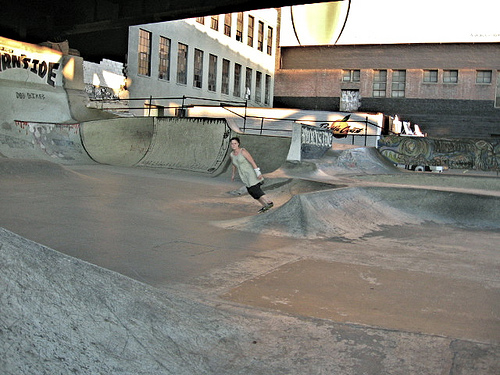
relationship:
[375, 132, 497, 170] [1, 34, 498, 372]
graffiti of skate park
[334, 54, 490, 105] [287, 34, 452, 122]
windows on building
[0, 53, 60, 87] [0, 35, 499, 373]
black letters in front a track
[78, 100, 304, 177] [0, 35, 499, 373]
ramp on track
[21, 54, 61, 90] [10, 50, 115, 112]
word: side on wall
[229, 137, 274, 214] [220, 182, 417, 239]
skateboarder skateboarding on ramp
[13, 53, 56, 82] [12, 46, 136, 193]
words on wall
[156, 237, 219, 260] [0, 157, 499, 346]
gray square on ground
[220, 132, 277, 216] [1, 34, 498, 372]
skateboarder in skate park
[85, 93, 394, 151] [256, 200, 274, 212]
railings in skateboard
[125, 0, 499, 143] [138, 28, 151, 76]
building with window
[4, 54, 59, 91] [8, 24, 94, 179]
name painted on wall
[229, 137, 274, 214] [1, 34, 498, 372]
skateboarder with skate park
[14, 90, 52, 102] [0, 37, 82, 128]
sign painted on wall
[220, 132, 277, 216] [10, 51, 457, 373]
skateboarder in skate park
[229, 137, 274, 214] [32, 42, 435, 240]
skateboarder in skate park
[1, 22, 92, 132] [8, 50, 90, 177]
painting on wall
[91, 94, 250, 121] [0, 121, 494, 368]
railing around skate park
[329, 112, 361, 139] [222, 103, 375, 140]
fruit painted on trailer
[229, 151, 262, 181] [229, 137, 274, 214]
top on skateboarder